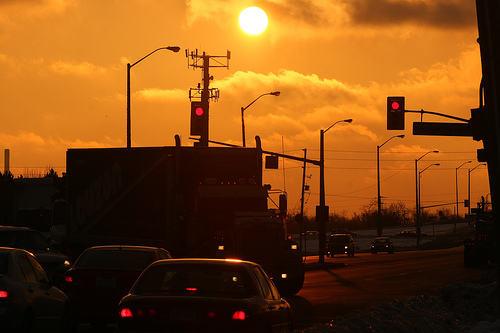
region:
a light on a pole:
[341, 73, 428, 130]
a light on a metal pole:
[379, 71, 417, 115]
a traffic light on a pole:
[376, 75, 467, 139]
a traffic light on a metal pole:
[357, 79, 487, 164]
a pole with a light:
[373, 73, 456, 153]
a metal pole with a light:
[358, 73, 465, 162]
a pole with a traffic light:
[377, 66, 469, 151]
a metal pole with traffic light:
[372, 55, 494, 165]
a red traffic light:
[358, 73, 472, 188]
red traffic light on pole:
[346, 64, 499, 194]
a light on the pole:
[375, 62, 472, 208]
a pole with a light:
[378, 63, 483, 164]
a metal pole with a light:
[366, 75, 483, 169]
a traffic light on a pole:
[387, 87, 485, 182]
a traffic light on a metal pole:
[361, 84, 493, 171]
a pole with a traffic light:
[374, 80, 493, 196]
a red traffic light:
[382, 82, 457, 165]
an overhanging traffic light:
[382, 91, 411, 133]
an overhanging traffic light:
[184, 96, 211, 137]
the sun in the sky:
[234, 3, 271, 35]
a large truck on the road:
[64, 127, 306, 293]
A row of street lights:
[119, 43, 484, 233]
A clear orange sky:
[0, 0, 499, 214]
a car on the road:
[117, 256, 296, 331]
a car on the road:
[63, 239, 170, 312]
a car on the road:
[0, 247, 72, 332]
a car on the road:
[323, 227, 355, 260]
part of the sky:
[4, 0, 72, 66]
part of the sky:
[3, 56, 60, 128]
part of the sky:
[61, 63, 121, 133]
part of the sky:
[17, 135, 65, 170]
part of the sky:
[282, 4, 344, 68]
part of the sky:
[353, 5, 418, 70]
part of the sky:
[293, 63, 366, 113]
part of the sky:
[330, 168, 365, 193]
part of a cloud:
[311, 88, 348, 104]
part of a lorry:
[216, 168, 235, 195]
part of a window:
[207, 269, 232, 305]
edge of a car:
[245, 285, 257, 311]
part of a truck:
[233, 201, 253, 234]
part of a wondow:
[208, 283, 223, 294]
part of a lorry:
[277, 206, 306, 227]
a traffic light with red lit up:
[385, 95, 404, 131]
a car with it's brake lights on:
[115, 258, 290, 332]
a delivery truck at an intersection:
[65, 146, 303, 298]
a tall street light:
[375, 133, 403, 234]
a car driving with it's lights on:
[367, 235, 392, 252]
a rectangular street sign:
[410, 120, 465, 135]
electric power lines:
[260, 145, 485, 166]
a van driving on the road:
[322, 230, 354, 257]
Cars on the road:
[18, 210, 361, 322]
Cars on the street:
[3, 211, 291, 320]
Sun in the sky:
[228, 7, 273, 38]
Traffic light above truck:
[173, 96, 221, 137]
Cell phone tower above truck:
[161, 45, 240, 132]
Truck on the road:
[50, 138, 325, 283]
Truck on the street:
[56, 138, 306, 285]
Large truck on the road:
[60, 139, 310, 276]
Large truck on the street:
[51, 143, 315, 283]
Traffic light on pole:
[386, 92, 481, 154]